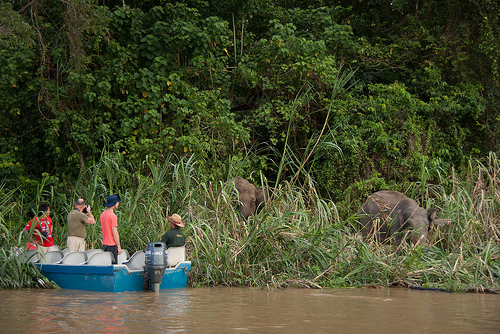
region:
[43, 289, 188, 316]
boat's reflection on the water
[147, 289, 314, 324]
muddy brown water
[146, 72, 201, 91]
yellow leaves on green tree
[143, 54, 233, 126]
green leaves on the tree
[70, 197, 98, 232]
black camera in man's hand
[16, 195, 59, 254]
hands folded at woman's waist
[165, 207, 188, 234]
brown hat on man's head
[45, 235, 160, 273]
white seats in blue boat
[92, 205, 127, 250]
man wearing orange shirt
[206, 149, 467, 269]
gray elephants eating grass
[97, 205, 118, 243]
Red shirt worn by young man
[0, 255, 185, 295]
Blue boat in the water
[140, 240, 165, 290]
Motor on back of boat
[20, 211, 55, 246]
Red shirt worn by young man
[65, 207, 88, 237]
Brown shirt worn by older man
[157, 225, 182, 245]
Green shirt worn by man sitting down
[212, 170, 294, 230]
First elephant in the bushes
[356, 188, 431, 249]
Elephant to the right laying in the bushes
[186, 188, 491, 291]
Tall grass on side of river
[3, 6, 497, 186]
Tall trees in background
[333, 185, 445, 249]
elephant in the bushes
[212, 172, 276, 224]
front of an elephant in the bushes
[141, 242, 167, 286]
motor of the boat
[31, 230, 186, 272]
chairs in the boat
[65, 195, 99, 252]
man taking a picture with his camera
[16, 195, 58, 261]
woman in a red shirt with a camera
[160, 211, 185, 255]
outback style brown hat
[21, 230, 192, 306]
blue river boat with charis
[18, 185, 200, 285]
group of people looking at elephants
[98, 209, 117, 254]
salmon colored t-shirt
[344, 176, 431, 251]
elephant hidden in the bushes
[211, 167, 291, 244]
front face of an elephant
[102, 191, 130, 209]
blue hat on mans head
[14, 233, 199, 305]
blue river boat with chairs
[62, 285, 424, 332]
brown water in the river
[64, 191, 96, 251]
man with camera taking pictures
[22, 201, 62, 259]
woman wearing a camera around her neck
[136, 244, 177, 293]
motor on the back of the boat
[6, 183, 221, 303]
four people in a boat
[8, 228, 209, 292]
small blue boat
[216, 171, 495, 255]
two elephants in tall grass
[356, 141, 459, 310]
elephant standing near river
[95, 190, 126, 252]
man in a pink shirt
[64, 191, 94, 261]
man taking a photograph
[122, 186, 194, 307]
man sitting in a boat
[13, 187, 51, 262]
man in a red shirt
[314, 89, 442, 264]
elephant standing on edge of forest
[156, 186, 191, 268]
man in straw hat